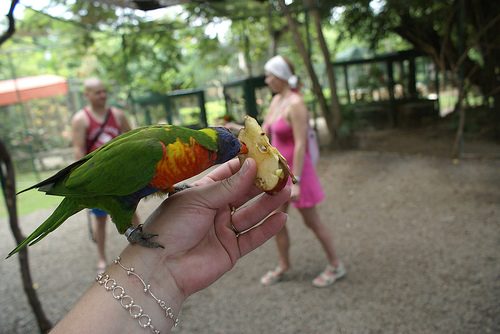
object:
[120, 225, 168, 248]
talons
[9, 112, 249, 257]
parrot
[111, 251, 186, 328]
bracelets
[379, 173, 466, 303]
floor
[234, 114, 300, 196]
fruit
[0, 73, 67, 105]
canopy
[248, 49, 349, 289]
woman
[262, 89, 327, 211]
dress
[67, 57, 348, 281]
man woman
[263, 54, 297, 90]
headband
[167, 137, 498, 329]
ground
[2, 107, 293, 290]
bird sitting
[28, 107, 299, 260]
bird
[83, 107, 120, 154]
shirt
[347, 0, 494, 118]
trees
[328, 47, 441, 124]
structures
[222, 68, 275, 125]
structures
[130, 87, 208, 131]
structures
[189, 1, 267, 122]
tree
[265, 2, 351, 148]
tree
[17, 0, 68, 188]
tree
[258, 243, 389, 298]
toes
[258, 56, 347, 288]
person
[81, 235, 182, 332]
wrist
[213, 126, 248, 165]
head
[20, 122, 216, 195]
feathers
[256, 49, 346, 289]
woman/sundress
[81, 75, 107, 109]
head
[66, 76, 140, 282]
people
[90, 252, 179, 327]
bracelet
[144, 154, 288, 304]
hand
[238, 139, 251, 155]
beak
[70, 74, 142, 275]
man